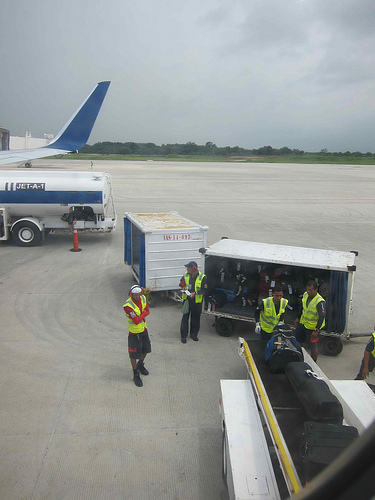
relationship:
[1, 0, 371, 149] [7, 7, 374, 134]
sky covered with clouds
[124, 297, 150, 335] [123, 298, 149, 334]
man wearing clothing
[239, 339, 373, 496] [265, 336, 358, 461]
baggage conveyor has bags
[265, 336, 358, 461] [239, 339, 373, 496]
bags are on baggage conveyor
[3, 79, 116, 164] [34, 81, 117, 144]
airliner has a wing tip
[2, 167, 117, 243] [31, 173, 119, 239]
fuel tanker has a back end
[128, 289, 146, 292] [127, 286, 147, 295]
ear muffs are on cap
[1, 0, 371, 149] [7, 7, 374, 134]
sky laden with clouds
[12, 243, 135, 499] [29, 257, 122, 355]
concrete has tire marks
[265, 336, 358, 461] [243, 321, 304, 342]
luggage being loaded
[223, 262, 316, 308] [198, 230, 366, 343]
luggage in cart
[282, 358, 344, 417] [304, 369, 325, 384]
luggage has tag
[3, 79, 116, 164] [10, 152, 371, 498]
plane on terminal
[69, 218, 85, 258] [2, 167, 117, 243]
cone by tank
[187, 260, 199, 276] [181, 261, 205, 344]
headphones are on man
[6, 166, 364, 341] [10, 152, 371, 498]
service vehicles are on ground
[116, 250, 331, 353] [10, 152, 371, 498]
airport employees are on ground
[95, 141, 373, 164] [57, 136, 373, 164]
trees are in distance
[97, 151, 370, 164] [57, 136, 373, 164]
grasses are in distance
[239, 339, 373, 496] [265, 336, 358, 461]
conveyor belt has suitcases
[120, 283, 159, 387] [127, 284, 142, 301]
employee wearing helmet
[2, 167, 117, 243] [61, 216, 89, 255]
tanker behind orange cone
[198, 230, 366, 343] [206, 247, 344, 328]
truck with luggage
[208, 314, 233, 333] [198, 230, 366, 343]
tire of truck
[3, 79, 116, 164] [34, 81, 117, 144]
plane has wing tip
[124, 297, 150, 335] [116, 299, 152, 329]
man in safety vest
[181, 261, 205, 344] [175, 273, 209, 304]
man in safety vest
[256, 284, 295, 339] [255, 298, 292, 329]
man in safety vest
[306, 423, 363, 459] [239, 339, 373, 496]
luggage on belt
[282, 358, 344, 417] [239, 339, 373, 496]
luggage on belt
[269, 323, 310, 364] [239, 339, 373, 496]
luggage on belt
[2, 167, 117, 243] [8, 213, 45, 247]
tanker truck has wheel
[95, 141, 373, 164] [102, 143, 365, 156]
trees are in line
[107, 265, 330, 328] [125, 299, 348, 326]
men are in vests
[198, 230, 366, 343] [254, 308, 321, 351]
vehicle being unloaded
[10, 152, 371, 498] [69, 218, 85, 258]
pavement has cone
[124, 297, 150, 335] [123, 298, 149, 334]
man in shirt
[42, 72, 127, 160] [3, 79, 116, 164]
tail on plane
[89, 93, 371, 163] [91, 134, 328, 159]
background has trees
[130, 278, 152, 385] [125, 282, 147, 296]
man has hat